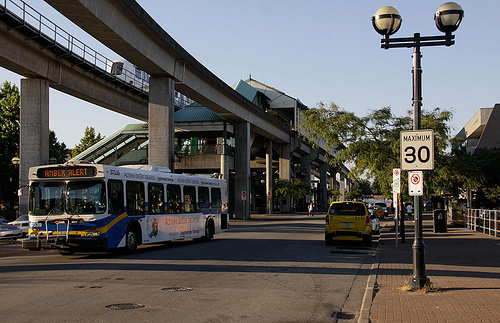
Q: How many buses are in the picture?
A: One.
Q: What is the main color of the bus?
A: White.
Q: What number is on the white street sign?
A: Thirty.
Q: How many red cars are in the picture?
A: Zero.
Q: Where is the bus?
A: On the street.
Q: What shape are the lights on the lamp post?
A: Round.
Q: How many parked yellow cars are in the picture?
A: One.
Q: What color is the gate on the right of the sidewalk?
A: White.